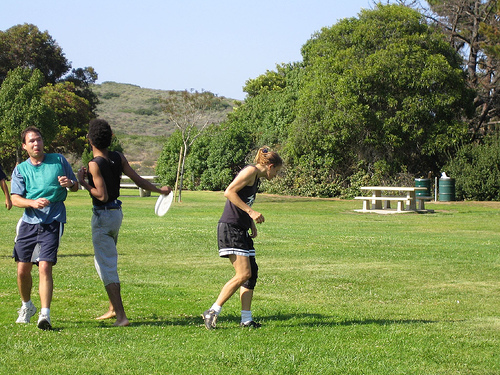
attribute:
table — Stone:
[359, 178, 426, 201]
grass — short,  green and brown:
[0, 330, 496, 371]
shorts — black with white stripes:
[214, 217, 259, 259]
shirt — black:
[213, 162, 255, 226]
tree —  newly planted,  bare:
[165, 111, 198, 195]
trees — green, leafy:
[152, 2, 474, 190]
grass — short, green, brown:
[1, 180, 498, 373]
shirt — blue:
[10, 151, 73, 225]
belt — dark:
[91, 196, 125, 216]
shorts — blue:
[13, 217, 62, 272]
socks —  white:
[229, 306, 262, 332]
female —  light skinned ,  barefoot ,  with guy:
[60, 111, 178, 318]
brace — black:
[241, 254, 258, 291]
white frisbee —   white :
[153, 184, 175, 220]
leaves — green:
[1, 0, 498, 200]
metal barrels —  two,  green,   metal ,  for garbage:
[416, 175, 431, 197]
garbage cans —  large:
[412, 166, 462, 208]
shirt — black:
[77, 152, 139, 214]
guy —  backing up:
[7, 125, 79, 330]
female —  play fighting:
[73, 116, 173, 330]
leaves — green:
[271, 83, 307, 103]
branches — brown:
[349, 133, 388, 158]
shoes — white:
[200, 306, 219, 327]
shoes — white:
[38, 315, 52, 330]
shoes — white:
[11, 301, 35, 324]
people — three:
[26, 119, 326, 329]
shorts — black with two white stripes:
[207, 211, 261, 263]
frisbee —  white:
[150, 184, 178, 219]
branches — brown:
[460, 3, 499, 136]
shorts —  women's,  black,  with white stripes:
[214, 223, 262, 260]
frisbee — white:
[149, 182, 179, 220]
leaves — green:
[360, 22, 409, 56]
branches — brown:
[345, 30, 415, 59]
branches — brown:
[307, 88, 354, 114]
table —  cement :
[350, 185, 411, 214]